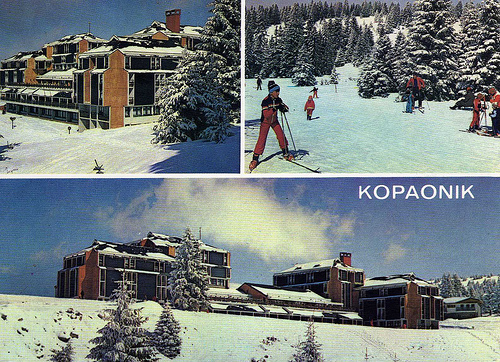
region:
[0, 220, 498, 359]
The ground is snow covered.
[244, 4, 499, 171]
The ground is snow covered.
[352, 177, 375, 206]
The letter is white.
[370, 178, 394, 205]
The letter is white.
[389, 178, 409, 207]
The letter is white.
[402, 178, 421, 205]
The letter is white.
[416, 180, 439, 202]
The letter is white.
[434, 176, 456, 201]
The letter is white.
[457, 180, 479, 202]
The letter is white.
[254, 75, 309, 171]
Person skiing up the hill.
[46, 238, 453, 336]
Ski lodge on the hill.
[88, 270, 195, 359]
Snow covered pine trees.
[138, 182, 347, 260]
Clouds in the sky.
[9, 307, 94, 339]
Snow covered rocks on the hill.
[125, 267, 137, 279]
Windows of the ski lodge.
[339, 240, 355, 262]
Chimney of the ski lodge.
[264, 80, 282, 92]
Hat on a boy's head.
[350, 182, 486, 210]
Name of a Russian city.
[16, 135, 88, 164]
Snow covered hill in front of lodge.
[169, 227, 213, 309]
a large pine tree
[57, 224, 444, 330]
a large building in the snow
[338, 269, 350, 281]
a window on the building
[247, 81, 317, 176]
a boy on skis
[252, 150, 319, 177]
a pair of skis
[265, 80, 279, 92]
a blue and black hat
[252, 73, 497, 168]
many people skiing together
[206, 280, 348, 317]
the snow covered roof of the low building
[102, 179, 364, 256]
a white puffy cloud in the sky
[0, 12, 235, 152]
a side view of the building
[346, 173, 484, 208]
a word written in white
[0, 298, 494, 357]
white snow on the ground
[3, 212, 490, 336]
a large green tree in front of building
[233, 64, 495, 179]
people skiing at resort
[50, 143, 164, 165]
ski tracks in the snow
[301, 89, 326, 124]
a child dressed in red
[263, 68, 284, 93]
a black and white and blue hat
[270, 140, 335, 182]
a foot in a ski shoe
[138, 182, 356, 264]
a large white cloud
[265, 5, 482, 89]
trees on a snowy hill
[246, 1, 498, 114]
Lots of snow covered pine trees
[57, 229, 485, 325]
Lots of snow on the roofs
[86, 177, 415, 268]
Big white cloud in the sky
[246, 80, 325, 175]
Skier with legs apart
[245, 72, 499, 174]
Lots of skiers on the slope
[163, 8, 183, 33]
Red brick chimney on the roof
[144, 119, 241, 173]
Shadow cast in the snow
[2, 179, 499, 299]
Lots of blue sky above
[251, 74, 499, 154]
Lots of people wearing red